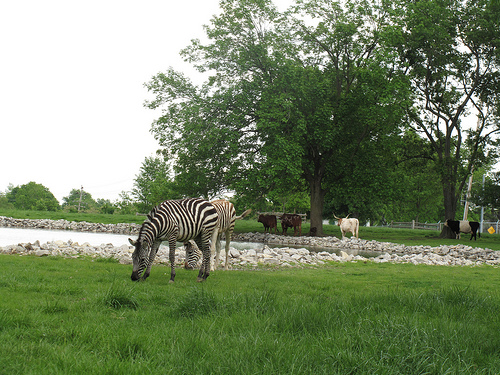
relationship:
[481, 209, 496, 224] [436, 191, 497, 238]
sign on fence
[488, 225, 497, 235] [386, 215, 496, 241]
sign on fence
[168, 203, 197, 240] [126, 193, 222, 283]
stripes on zebra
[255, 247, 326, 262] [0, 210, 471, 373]
rocks on ground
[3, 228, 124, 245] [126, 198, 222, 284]
water next zebra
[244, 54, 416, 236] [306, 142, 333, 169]
tree has leaves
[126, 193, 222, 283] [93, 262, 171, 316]
zebra eats grass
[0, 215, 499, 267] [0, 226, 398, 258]
piles near water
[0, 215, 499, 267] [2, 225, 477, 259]
piles around water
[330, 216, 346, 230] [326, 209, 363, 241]
patch on cattle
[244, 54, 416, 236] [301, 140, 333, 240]
tree has trunk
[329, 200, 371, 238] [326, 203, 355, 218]
cattle has horns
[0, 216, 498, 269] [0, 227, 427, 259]
rocks around pond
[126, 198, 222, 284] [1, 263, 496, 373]
zebra eats grass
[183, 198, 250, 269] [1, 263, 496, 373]
zebra eats grass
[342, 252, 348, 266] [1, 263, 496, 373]
rocks near grass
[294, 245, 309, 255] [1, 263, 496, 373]
rocks near grass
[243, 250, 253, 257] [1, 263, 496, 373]
rocks near grass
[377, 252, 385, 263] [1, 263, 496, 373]
rocks near grass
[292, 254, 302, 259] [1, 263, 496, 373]
rocks near grass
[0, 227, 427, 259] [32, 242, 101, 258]
pond near rocks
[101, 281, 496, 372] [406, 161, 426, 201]
grass on ground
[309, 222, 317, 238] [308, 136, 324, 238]
black spot on tree trunk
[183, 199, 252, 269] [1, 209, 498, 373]
zebra grazing on grass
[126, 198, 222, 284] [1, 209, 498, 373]
zebra grazing on grass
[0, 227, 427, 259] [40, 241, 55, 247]
pond near rocks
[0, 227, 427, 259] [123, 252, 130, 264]
pond near rocks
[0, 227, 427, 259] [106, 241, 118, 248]
pond near rocks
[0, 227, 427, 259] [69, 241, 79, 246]
pond near rocks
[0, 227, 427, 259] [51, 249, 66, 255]
pond near rocks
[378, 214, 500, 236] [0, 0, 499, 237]
fence in background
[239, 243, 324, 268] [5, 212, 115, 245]
rocks are near pond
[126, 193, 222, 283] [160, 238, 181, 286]
zebra has leg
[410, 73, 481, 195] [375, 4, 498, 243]
branches on tree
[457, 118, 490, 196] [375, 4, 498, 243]
branch on tree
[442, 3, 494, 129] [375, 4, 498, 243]
branch on tree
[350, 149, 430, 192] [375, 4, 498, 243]
branch on tree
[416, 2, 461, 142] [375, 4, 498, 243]
branch on tree